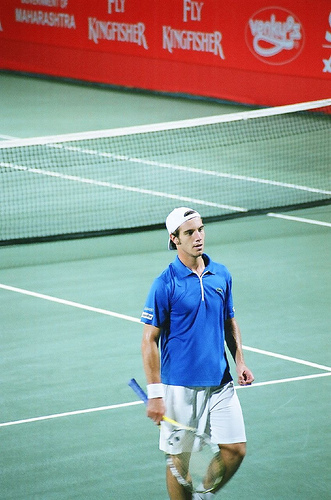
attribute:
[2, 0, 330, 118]
banner — promotional, red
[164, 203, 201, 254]
cap — white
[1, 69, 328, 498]
court — green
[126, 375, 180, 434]
handle — blue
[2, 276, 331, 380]
line — white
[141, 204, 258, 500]
man — male, walking, young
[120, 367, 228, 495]
racket — blue, yellow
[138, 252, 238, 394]
shirt — blue, short sleeved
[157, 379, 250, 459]
shorts — white, men's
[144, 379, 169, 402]
wrist band — white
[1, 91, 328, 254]
net — stretched